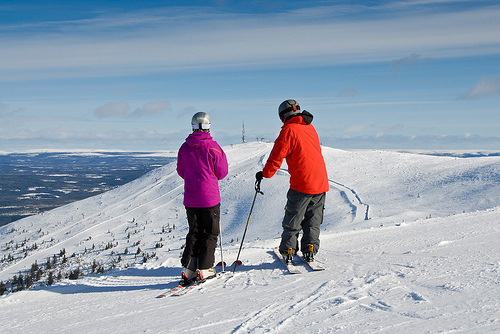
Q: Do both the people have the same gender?
A: No, they are both male and female.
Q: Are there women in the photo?
A: Yes, there is a woman.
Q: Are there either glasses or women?
A: Yes, there is a woman.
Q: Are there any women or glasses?
A: Yes, there is a woman.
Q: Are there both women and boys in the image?
A: No, there is a woman but no boys.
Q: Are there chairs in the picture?
A: No, there are no chairs.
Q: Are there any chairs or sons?
A: No, there are no chairs or sons.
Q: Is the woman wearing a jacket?
A: Yes, the woman is wearing a jacket.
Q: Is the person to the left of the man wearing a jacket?
A: Yes, the woman is wearing a jacket.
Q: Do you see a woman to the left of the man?
A: Yes, there is a woman to the left of the man.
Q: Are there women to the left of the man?
A: Yes, there is a woman to the left of the man.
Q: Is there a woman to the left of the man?
A: Yes, there is a woman to the left of the man.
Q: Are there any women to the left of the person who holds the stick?
A: Yes, there is a woman to the left of the man.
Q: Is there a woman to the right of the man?
A: No, the woman is to the left of the man.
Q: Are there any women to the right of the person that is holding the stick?
A: No, the woman is to the left of the man.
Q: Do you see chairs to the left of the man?
A: No, there is a woman to the left of the man.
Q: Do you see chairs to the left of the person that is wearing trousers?
A: No, there is a woman to the left of the man.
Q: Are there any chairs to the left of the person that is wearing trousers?
A: No, there is a woman to the left of the man.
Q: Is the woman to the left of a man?
A: Yes, the woman is to the left of a man.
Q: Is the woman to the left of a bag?
A: No, the woman is to the left of a man.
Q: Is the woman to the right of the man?
A: No, the woman is to the left of the man.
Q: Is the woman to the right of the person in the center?
A: No, the woman is to the left of the man.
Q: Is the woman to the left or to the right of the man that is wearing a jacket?
A: The woman is to the left of the man.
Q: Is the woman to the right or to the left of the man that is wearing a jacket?
A: The woman is to the left of the man.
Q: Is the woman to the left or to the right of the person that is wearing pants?
A: The woman is to the left of the man.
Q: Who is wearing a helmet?
A: The woman is wearing a helmet.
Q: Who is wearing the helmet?
A: The woman is wearing a helmet.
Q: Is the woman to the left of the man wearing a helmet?
A: Yes, the woman is wearing a helmet.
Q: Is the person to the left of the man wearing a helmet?
A: Yes, the woman is wearing a helmet.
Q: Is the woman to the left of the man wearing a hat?
A: No, the woman is wearing a helmet.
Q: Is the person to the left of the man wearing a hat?
A: No, the woman is wearing a helmet.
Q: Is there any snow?
A: Yes, there is snow.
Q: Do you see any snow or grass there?
A: Yes, there is snow.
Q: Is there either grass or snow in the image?
A: Yes, there is snow.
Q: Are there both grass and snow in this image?
A: No, there is snow but no grass.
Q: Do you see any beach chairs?
A: No, there are no beach chairs.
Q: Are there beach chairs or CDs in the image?
A: No, there are no beach chairs or cds.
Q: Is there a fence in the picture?
A: No, there are no fences.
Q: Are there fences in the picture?
A: No, there are no fences.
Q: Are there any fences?
A: No, there are no fences.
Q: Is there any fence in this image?
A: No, there are no fences.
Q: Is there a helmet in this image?
A: Yes, there is a helmet.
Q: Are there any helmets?
A: Yes, there is a helmet.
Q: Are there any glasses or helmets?
A: Yes, there is a helmet.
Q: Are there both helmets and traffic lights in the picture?
A: No, there is a helmet but no traffic lights.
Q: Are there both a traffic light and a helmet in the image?
A: No, there is a helmet but no traffic lights.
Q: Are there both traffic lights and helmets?
A: No, there is a helmet but no traffic lights.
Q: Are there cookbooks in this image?
A: No, there are no cookbooks.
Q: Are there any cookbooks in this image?
A: No, there are no cookbooks.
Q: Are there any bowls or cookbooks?
A: No, there are no cookbooks or bowls.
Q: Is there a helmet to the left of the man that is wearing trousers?
A: Yes, there is a helmet to the left of the man.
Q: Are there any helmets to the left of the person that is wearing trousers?
A: Yes, there is a helmet to the left of the man.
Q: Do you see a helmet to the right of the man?
A: No, the helmet is to the left of the man.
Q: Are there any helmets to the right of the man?
A: No, the helmet is to the left of the man.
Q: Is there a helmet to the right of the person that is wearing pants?
A: No, the helmet is to the left of the man.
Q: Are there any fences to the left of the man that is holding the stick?
A: No, there is a helmet to the left of the man.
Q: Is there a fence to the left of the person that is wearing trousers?
A: No, there is a helmet to the left of the man.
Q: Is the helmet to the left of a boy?
A: No, the helmet is to the left of the man.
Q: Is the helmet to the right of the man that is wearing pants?
A: No, the helmet is to the left of the man.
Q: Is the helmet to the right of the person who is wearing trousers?
A: No, the helmet is to the left of the man.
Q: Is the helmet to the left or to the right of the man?
A: The helmet is to the left of the man.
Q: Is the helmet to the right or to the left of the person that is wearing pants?
A: The helmet is to the left of the man.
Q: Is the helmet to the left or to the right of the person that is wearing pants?
A: The helmet is to the left of the man.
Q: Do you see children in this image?
A: No, there are no children.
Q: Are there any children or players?
A: No, there are no children or players.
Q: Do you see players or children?
A: No, there are no children or players.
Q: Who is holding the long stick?
A: The man is holding the stick.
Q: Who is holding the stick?
A: The man is holding the stick.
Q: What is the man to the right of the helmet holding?
A: The man is holding the stick.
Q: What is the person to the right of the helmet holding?
A: The man is holding the stick.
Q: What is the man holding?
A: The man is holding the stick.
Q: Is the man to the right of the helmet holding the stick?
A: Yes, the man is holding the stick.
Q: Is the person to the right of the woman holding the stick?
A: Yes, the man is holding the stick.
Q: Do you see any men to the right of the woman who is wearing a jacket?
A: Yes, there is a man to the right of the woman.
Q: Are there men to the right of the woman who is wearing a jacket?
A: Yes, there is a man to the right of the woman.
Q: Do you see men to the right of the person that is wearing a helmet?
A: Yes, there is a man to the right of the woman.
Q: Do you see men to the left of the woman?
A: No, the man is to the right of the woman.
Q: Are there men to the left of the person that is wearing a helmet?
A: No, the man is to the right of the woman.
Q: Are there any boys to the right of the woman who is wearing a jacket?
A: No, there is a man to the right of the woman.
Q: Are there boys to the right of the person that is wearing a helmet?
A: No, there is a man to the right of the woman.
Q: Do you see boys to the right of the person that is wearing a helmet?
A: No, there is a man to the right of the woman.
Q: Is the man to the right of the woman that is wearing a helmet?
A: Yes, the man is to the right of the woman.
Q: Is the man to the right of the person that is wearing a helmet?
A: Yes, the man is to the right of the woman.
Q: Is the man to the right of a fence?
A: No, the man is to the right of the woman.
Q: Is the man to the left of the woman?
A: No, the man is to the right of the woman.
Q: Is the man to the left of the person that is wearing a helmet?
A: No, the man is to the right of the woman.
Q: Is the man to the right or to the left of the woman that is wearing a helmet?
A: The man is to the right of the woman.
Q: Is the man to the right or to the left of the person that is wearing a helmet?
A: The man is to the right of the woman.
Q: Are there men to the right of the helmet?
A: Yes, there is a man to the right of the helmet.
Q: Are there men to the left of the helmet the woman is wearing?
A: No, the man is to the right of the helmet.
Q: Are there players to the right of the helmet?
A: No, there is a man to the right of the helmet.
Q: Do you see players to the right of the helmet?
A: No, there is a man to the right of the helmet.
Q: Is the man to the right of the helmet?
A: Yes, the man is to the right of the helmet.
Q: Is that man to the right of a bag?
A: No, the man is to the right of the helmet.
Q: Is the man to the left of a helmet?
A: No, the man is to the right of a helmet.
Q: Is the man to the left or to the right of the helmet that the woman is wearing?
A: The man is to the right of the helmet.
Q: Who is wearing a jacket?
A: The man is wearing a jacket.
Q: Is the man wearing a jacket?
A: Yes, the man is wearing a jacket.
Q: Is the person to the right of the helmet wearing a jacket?
A: Yes, the man is wearing a jacket.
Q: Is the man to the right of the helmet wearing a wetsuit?
A: No, the man is wearing a jacket.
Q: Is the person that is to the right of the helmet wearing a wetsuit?
A: No, the man is wearing a jacket.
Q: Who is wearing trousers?
A: The man is wearing trousers.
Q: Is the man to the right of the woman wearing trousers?
A: Yes, the man is wearing trousers.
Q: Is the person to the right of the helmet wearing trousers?
A: Yes, the man is wearing trousers.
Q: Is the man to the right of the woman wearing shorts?
A: No, the man is wearing trousers.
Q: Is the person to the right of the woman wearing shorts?
A: No, the man is wearing trousers.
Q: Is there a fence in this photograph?
A: No, there are no fences.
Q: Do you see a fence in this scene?
A: No, there are no fences.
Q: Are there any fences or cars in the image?
A: No, there are no fences or cars.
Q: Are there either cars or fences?
A: No, there are no fences or cars.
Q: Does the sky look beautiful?
A: Yes, the sky is beautiful.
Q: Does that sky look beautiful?
A: Yes, the sky is beautiful.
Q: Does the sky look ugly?
A: No, the sky is beautiful.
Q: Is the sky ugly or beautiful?
A: The sky is beautiful.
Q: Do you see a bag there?
A: No, there are no bags.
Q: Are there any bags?
A: No, there are no bags.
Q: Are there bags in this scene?
A: No, there are no bags.